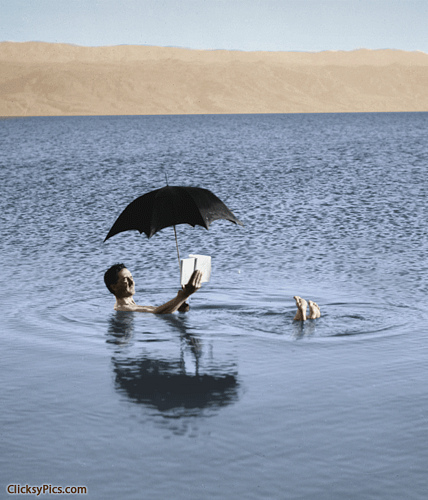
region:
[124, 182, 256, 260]
Person holding umbrella.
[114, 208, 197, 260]
Umbrella is black in color.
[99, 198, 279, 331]
Umbrella is providing shade for man.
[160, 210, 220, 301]
Umbrella has silver pole.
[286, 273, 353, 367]
Man's feet are sticking above water.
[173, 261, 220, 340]
Man is holding book.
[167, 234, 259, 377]
Man is reading book.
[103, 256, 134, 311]
Man has dark hair.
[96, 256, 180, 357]
Man has short hair.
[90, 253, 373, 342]
Man is sitting in water.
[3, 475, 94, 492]
ClicksyPics.com written on photo.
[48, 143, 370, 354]
Man reading a book and holding an umbrella.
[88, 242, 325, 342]
Man reading a book.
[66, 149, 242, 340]
Man holding an umbrella.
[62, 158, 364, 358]
Man lying in the water.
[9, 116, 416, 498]
The water appears blue.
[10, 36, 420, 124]
Brown sand in the background.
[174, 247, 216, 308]
Book held in man's right hand.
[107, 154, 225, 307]
The umbrella is black.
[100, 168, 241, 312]
Umbrella in man's left hand.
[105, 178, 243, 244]
a black umbrella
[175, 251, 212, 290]
a white book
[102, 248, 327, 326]
man floating in water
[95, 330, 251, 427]
shadow of umbrella in water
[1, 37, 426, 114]
brown mountains in background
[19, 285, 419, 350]
ripples in the water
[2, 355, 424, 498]
calm smooth blue water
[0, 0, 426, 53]
clear light blue sky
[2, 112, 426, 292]
dark blue ripply water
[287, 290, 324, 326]
two feet sticking out of water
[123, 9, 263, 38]
this is the sky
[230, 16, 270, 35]
the sky is blue in color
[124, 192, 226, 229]
this is an umbrella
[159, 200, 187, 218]
the umbrella is black in color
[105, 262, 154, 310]
this is a man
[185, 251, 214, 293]
this is a book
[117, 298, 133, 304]
the man is light skinned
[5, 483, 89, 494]
this is a writing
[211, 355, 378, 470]
this is the water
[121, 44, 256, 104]
this is a hill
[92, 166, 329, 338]
man floating in water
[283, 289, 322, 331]
feet sticking out of water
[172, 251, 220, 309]
book in man's hand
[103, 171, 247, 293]
black umbrella over man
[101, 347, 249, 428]
reflection of umbrella in water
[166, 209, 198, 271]
pole underneath open umbrella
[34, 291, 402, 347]
ripples in water around man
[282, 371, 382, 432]
light reflection on water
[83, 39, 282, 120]
mountain range in distance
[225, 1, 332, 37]
clear blue daytime sky